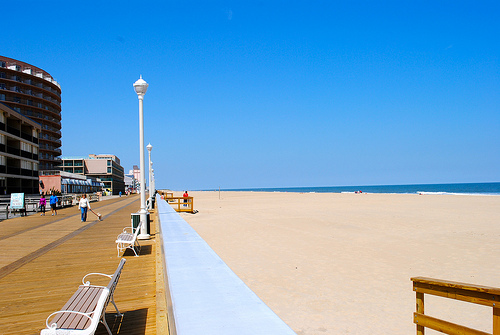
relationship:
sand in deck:
[157, 189, 499, 334] [8, 162, 164, 334]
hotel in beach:
[0, 57, 63, 197] [157, 188, 499, 331]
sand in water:
[157, 189, 499, 334] [176, 181, 498, 196]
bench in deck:
[45, 258, 135, 334] [2, 180, 172, 334]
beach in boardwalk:
[157, 178, 497, 319] [0, 193, 171, 335]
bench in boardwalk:
[41, 258, 125, 335] [0, 169, 176, 328]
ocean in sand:
[189, 182, 499, 196] [157, 189, 499, 334]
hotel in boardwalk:
[5, 54, 67, 212] [1, 172, 281, 332]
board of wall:
[146, 186, 298, 333] [142, 185, 308, 334]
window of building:
[16, 140, 27, 151] [3, 108, 43, 205]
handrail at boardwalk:
[382, 270, 493, 318] [0, 189, 171, 334]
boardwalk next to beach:
[0, 189, 171, 334] [157, 188, 499, 331]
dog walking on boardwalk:
[90, 208, 111, 222] [0, 189, 171, 334]